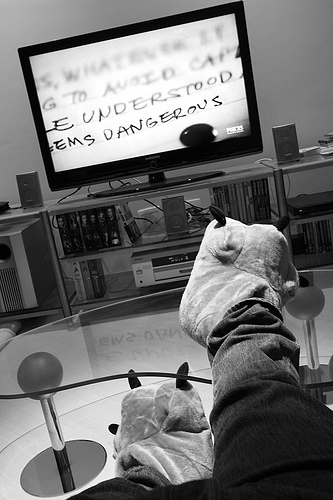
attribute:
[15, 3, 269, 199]
tv — on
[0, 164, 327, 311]
shelves — metal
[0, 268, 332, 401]
table(clear) — black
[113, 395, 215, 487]
animal slipper — furry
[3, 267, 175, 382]
table —  glass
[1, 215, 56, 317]
speaker — silver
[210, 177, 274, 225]
dvd — series 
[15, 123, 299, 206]
speaker — small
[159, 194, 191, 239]
speaker — portable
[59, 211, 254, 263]
shelf — second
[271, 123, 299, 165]
speaker — set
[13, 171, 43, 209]
speaker — set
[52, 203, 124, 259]
tapes — VHS , movies 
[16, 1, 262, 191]
television set — wide